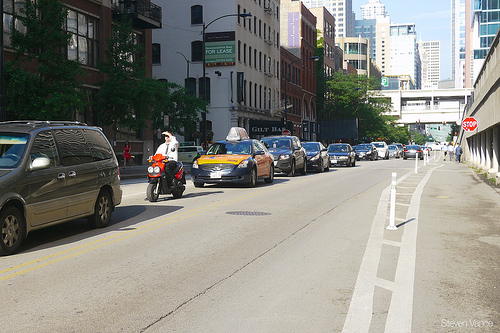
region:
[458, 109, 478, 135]
The sign is red and white.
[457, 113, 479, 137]
The sign is octagonal.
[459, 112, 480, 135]
The sign has lettering.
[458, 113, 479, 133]
Lettering on sign is white.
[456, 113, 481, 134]
Lettering on sign is printed.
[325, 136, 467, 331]
White lines painted on the street.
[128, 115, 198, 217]
The man is shielding his eyes.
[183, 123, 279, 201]
The car is yellow and black.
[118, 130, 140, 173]
The woman is walking.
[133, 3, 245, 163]
Sign is hanging on side of building.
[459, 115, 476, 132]
A red and white stop sign.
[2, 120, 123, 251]
A dark grey minivan.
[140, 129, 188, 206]
A person on a scooter, on the street.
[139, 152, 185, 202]
An orange scooter.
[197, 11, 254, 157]
A street light.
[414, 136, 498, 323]
People walking along a sidewalk.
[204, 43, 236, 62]
A green and white sign on the side of a building.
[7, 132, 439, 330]
The street.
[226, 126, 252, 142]
A white sign on top of a car.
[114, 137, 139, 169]
A woman dressed in red on the sidewalk.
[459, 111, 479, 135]
Red stop sign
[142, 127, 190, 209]
man riding on red scooter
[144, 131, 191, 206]
man covering eyes from sun while driving scooter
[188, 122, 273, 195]
black and yellow taxi cab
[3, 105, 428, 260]
long stretch of vehicles stuck in traffic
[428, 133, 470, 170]
people walking on side of street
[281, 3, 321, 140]
tall red brick building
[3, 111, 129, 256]
grey van on road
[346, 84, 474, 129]
pedestrian walkway above street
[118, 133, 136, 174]
woman dressed in red walking on sidewalk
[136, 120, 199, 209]
a man on a scooter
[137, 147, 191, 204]
a red scooter behind a van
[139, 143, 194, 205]
a red scooter in front of a taxi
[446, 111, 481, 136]
a stop sign on the side of the road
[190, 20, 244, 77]
a for lease sign on the side of a building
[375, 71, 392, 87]
a green parking sign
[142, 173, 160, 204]
the front wheel of the scooter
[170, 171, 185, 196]
the back wheel of the scooter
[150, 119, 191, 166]
a man wearing a white shirt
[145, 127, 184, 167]
a man wearing a tie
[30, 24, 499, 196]
a picture of a city street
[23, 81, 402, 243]
traffic on the street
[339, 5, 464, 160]
buildings in the background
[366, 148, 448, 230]
dividers on the street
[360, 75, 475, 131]
a bridge between buidings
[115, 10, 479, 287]
the sun is shining in tis picture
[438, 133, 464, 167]
people walkingby the street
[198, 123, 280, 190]
a cab on the road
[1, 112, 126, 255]
a minivan ahead of the traffic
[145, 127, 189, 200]
this man is on a red scooter